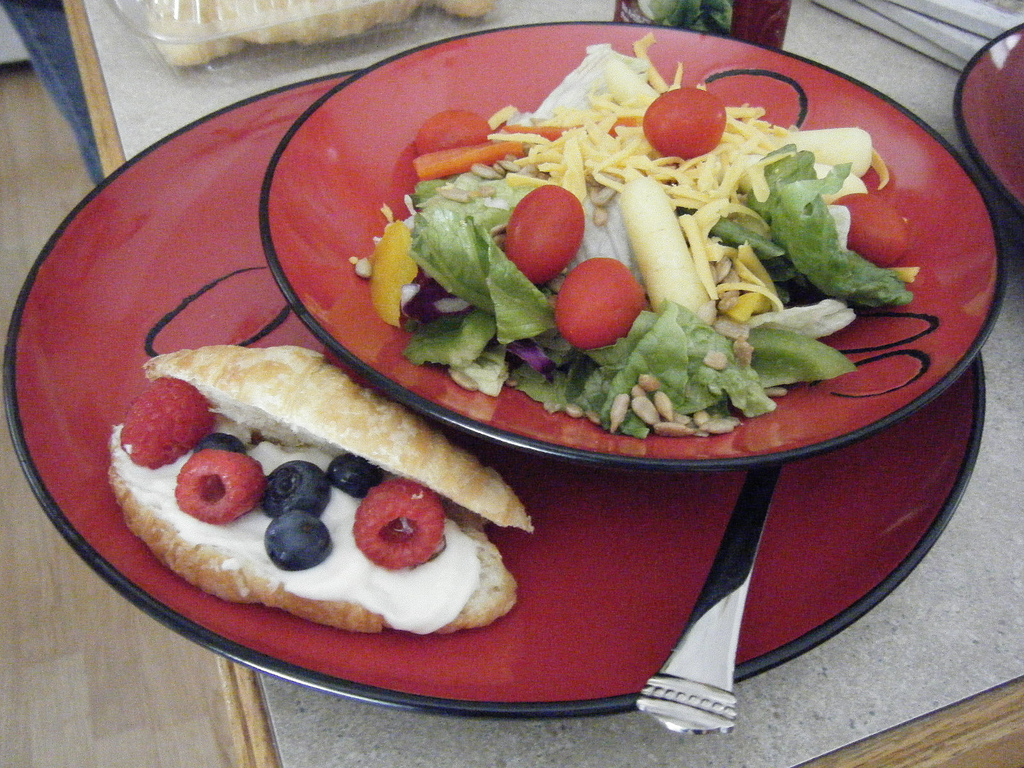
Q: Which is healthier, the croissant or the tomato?
A: The tomato is healthier than the croissant.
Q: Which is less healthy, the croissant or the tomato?
A: The croissant is less healthy than the tomato.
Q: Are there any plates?
A: Yes, there is a plate.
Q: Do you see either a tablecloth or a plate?
A: Yes, there is a plate.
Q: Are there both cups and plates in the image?
A: No, there is a plate but no cups.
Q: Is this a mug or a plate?
A: This is a plate.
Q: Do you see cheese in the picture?
A: Yes, there is cheese.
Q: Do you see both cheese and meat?
A: No, there is cheese but no meat.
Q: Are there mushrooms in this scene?
A: No, there are no mushrooms.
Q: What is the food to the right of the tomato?
A: The food is cheese.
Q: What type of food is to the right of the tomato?
A: The food is cheese.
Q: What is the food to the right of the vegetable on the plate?
A: The food is cheese.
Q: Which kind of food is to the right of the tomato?
A: The food is cheese.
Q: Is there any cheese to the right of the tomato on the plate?
A: Yes, there is cheese to the right of the tomato.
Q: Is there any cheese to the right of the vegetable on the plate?
A: Yes, there is cheese to the right of the tomato.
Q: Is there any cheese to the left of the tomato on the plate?
A: No, the cheese is to the right of the tomato.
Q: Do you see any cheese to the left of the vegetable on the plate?
A: No, the cheese is to the right of the tomato.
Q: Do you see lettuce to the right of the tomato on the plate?
A: No, there is cheese to the right of the tomato.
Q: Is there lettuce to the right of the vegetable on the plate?
A: No, there is cheese to the right of the tomato.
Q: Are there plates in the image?
A: Yes, there is a plate.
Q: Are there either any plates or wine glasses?
A: Yes, there is a plate.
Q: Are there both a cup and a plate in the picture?
A: No, there is a plate but no cups.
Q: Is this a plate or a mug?
A: This is a plate.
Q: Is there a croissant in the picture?
A: Yes, there is a croissant.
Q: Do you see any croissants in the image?
A: Yes, there is a croissant.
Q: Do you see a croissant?
A: Yes, there is a croissant.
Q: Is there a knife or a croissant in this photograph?
A: Yes, there is a croissant.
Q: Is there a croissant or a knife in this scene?
A: Yes, there is a croissant.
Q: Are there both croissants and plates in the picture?
A: Yes, there are both a croissant and a plate.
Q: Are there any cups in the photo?
A: No, there are no cups.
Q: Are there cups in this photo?
A: No, there are no cups.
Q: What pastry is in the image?
A: The pastry is a croissant.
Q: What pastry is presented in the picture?
A: The pastry is a croissant.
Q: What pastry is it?
A: The pastry is a croissant.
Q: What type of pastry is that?
A: This is a croissant.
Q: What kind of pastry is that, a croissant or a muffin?
A: This is a croissant.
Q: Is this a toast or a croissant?
A: This is a croissant.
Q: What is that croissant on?
A: The croissant is on the plate.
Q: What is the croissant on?
A: The croissant is on the plate.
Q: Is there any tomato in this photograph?
A: Yes, there is a tomato.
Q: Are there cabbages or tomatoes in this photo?
A: Yes, there is a tomato.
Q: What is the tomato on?
A: The tomato is on the plate.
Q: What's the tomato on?
A: The tomato is on the plate.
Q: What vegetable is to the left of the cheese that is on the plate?
A: The vegetable is a tomato.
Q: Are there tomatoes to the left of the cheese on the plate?
A: Yes, there is a tomato to the left of the cheese.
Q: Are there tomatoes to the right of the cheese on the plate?
A: No, the tomato is to the left of the cheese.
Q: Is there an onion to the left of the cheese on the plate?
A: No, there is a tomato to the left of the cheese.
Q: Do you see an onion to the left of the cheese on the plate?
A: No, there is a tomato to the left of the cheese.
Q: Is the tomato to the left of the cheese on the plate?
A: Yes, the tomato is to the left of the cheese.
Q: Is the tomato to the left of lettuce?
A: No, the tomato is to the left of the cheese.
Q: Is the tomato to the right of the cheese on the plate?
A: No, the tomato is to the left of the cheese.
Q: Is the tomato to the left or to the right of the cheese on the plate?
A: The tomato is to the left of the cheese.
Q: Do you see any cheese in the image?
A: Yes, there is cheese.